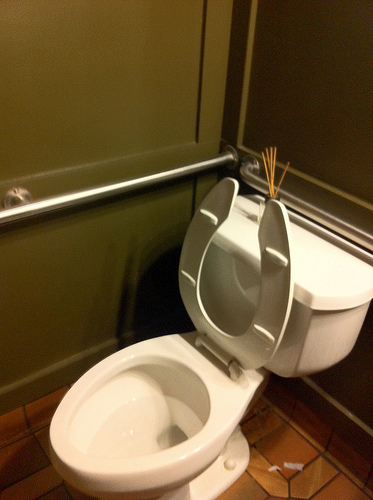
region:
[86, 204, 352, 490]
view is in a bthroom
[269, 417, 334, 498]
floor is brown in colr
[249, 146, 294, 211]
the wooden sticks are on the toilet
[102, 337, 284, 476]
the toilet is clean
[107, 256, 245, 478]
the toilet seat is open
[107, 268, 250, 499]
the toilet is white in color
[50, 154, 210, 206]
the metal rode is silvery in color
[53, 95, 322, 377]
the room is dark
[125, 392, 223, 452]
the toilt has water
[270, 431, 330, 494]
the floor has brown tiles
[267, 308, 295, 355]
edge of a lid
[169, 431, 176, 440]
part fo a water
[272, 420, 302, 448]
part f a floor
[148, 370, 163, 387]
part of a shade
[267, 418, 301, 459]
part of a floor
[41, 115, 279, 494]
toilet in the bathroom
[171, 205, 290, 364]
seat of the toilet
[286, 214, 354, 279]
tank of the toilet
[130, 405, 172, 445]
water in the toilet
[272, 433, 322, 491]
tile on the floor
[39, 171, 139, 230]
railing on the wall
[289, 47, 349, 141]
the wall is green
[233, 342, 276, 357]
underside of the seat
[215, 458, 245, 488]
bottom of the toilet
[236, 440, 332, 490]
the floor is brown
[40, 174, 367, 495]
this is a toilet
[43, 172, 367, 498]
this is a white toilet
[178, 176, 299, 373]
this is a toilet seat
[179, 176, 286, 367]
this is a white toilet seat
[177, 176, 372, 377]
this is a cistern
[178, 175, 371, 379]
this is a white cistern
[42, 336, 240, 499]
this is a toilet bowl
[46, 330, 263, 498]
this is a white toilet bowl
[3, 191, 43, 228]
this is a metal rod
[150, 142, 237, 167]
this is a metal rod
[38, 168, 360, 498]
White color western type toilet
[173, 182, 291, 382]
Lid of the western toilet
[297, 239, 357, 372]
White color tank of the western toilet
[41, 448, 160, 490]
white color bowl of the western toilet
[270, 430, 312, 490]
Brown color floor tiles of the bath room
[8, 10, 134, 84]
green color wall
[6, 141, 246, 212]
Silver color hanger attached in the wall